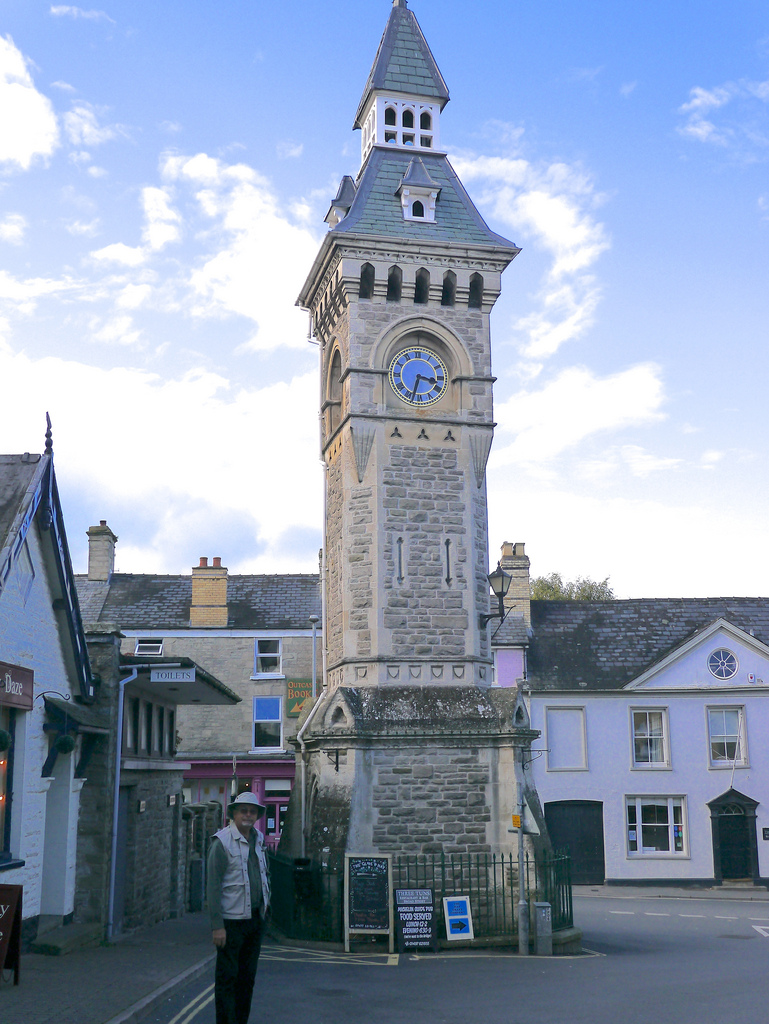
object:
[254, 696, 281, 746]
window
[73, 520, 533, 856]
building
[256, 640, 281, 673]
window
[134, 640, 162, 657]
window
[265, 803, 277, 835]
window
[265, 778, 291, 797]
window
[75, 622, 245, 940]
building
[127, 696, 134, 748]
window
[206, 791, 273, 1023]
man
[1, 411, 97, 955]
building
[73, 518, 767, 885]
building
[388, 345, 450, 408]
clock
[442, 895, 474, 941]
sign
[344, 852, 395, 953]
sign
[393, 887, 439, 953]
sign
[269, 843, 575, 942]
fence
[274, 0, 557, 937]
tower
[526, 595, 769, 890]
building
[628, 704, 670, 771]
window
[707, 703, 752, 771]
window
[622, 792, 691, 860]
window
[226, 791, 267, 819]
hat